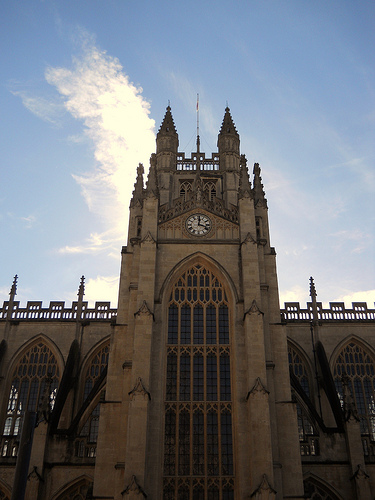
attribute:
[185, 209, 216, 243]
clock — white, large, circular, round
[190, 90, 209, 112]
flag — large, hanging, red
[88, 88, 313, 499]
building — cathedral style, brown, old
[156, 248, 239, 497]
cathedral window — long, arched, large, segmented, central, glass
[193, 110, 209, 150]
spire — steel, tallest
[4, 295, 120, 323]
railing — stone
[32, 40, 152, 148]
cloud — white, stormy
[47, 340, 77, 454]
railing — black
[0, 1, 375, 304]
sky — blue, overhead, clear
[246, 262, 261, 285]
spot — square, large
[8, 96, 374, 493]
design — decorative, triangular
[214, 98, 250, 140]
spiral — tall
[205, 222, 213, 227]
roman numerals — black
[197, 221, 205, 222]
hands — black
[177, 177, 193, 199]
window — glass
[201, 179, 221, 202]
window — glass